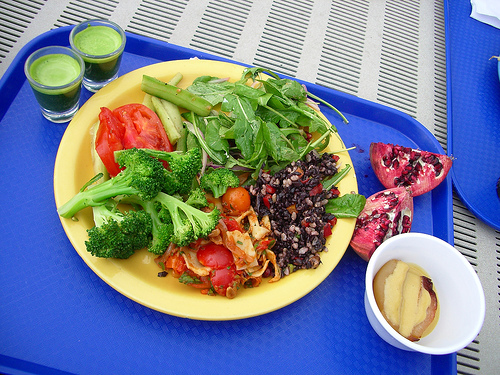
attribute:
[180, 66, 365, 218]
spinach — green, fresh, leaves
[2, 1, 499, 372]
table — white, notched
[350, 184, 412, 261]
pomegranate — sliced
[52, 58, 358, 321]
plate — yellow, round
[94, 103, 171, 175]
tomatoes — sliced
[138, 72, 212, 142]
celery — sliced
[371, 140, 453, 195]
pomegranate — wedged, sliced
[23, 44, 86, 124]
glass — clear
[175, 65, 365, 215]
salad — green, piled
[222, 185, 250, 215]
cherry tomato — reddish orange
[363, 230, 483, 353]
bowl — small, white, filled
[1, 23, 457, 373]
tray — blue, plastic, yellow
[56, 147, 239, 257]
broccoli — green, yellow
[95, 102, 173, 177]
tomato — red, sliced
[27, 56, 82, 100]
juice — green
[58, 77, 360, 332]
plate — in clear view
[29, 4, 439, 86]
stand — iron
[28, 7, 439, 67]
stand — iron